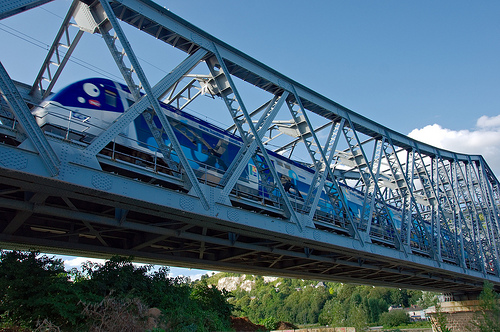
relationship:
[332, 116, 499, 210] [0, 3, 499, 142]
cloud in blue sky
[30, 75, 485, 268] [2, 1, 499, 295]
train traveling on bridge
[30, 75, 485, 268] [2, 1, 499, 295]
train on bridge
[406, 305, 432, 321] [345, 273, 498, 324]
house in distance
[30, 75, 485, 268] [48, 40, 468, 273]
train over bridge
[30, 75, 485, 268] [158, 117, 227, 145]
train carrying passengers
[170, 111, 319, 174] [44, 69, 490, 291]
windows on train